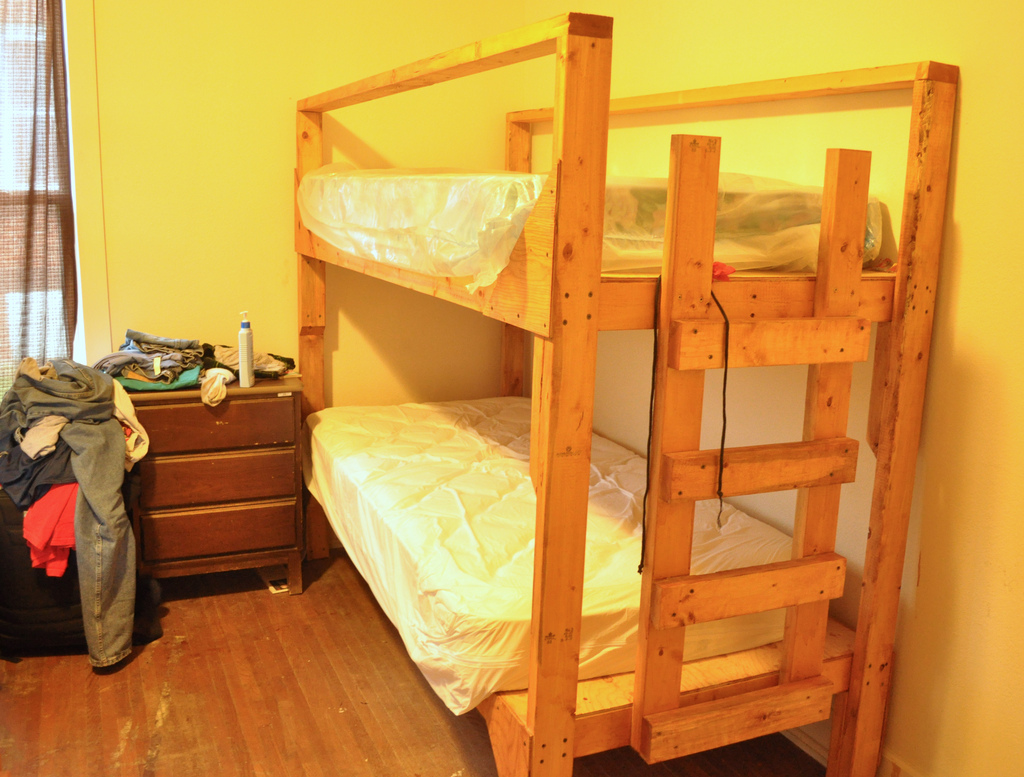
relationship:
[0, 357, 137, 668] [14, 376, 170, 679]
pants of clothing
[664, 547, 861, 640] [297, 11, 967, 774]
slat on bed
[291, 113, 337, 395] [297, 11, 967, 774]
slat on bed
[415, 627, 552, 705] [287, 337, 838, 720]
mattress protector on a mattress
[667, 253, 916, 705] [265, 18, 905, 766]
ladder on a bunk bed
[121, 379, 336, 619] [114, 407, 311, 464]
dresser with drawer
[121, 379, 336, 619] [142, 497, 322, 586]
dresser with drawer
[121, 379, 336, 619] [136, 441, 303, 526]
dresser with drawer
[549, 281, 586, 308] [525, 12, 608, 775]
screw in a piece of leg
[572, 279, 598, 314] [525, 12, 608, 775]
screw in a piece of leg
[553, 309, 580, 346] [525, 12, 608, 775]
screw in a piece of leg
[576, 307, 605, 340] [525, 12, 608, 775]
screw in a piece of leg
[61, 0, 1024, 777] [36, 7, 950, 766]
wall on side of a building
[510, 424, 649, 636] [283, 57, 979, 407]
leg of bed